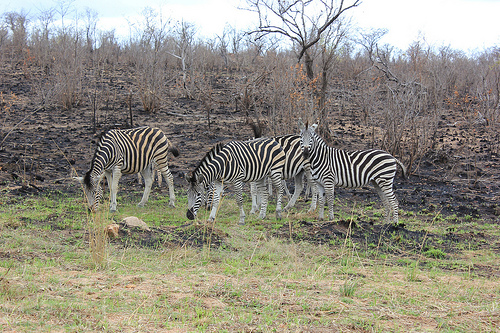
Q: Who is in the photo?
A: Nobody.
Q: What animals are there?
A: Zebras.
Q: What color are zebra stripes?
A: Black.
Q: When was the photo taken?
A: Daytime.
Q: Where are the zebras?
A: In the pasture.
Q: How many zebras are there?
A: Four.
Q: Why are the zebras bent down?
A: They are grazing.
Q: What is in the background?
A: Trees.